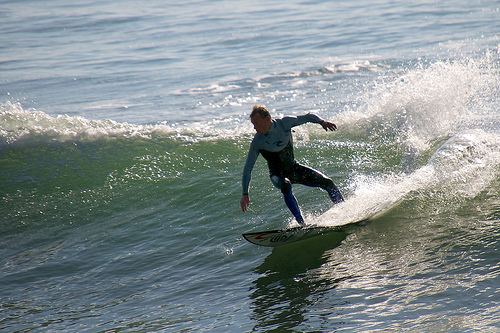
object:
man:
[239, 104, 345, 226]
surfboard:
[242, 221, 359, 258]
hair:
[248, 104, 272, 122]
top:
[241, 112, 322, 195]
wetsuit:
[241, 112, 345, 224]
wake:
[314, 163, 426, 232]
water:
[3, 3, 499, 332]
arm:
[282, 112, 323, 133]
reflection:
[250, 226, 348, 332]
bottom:
[242, 230, 320, 250]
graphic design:
[268, 233, 296, 247]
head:
[250, 107, 271, 136]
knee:
[277, 175, 297, 195]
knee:
[320, 174, 336, 191]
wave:
[5, 95, 500, 248]